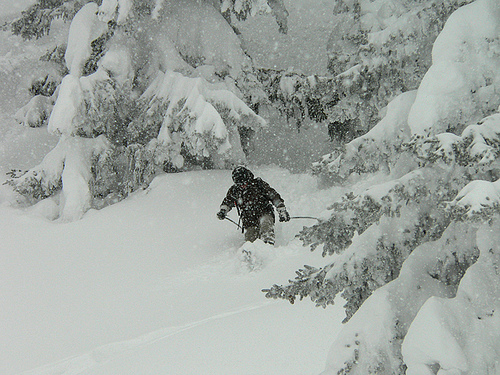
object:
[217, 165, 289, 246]
person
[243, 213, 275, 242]
pants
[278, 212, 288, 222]
hand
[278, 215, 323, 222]
ski pole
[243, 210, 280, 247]
silver knob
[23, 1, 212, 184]
woods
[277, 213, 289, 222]
glove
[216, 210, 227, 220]
glove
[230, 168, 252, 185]
goggles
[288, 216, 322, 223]
pole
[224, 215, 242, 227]
pole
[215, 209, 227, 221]
black gloves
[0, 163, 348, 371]
hill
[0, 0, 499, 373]
wooded area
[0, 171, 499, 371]
hill side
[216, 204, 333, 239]
sticks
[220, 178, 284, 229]
coat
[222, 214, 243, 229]
ski pole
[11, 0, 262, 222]
snowy tree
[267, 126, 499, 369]
snowy tree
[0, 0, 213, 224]
tree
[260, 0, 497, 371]
tree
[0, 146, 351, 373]
snow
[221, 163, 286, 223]
ski jacket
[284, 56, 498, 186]
tree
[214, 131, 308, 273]
ski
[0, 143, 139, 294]
side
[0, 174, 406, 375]
ground